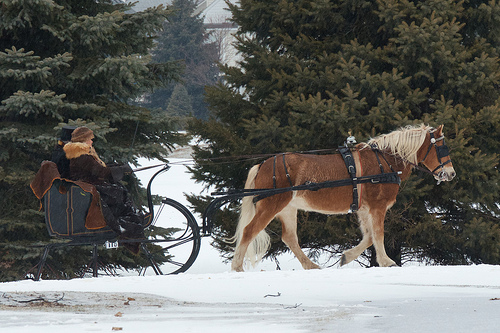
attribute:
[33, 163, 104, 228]
fabric — brown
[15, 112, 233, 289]
carriage — green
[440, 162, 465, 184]
nose — white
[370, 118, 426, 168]
mane — beige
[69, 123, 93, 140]
cap — brown, furry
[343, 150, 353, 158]
metal buckles — metallic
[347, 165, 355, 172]
metal buckles — metallic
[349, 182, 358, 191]
metal buckles — metallic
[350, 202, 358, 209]
metal buckles — metallic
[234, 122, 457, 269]
horse — brown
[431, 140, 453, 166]
blinder — black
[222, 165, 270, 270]
tail — long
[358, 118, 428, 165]
long hair — white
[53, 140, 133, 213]
coat — fur-collared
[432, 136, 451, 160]
flap — black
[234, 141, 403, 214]
harness — black